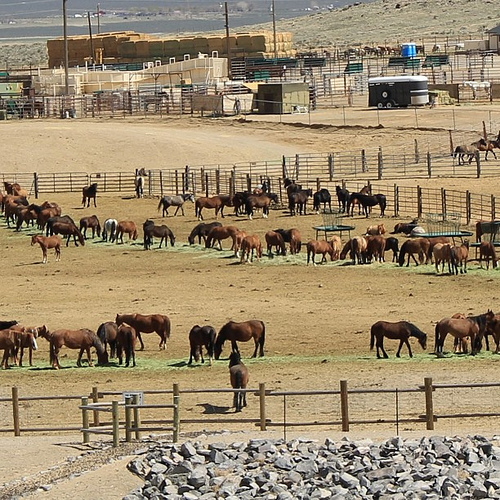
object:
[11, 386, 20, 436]
pole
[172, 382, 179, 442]
pole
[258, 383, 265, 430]
pole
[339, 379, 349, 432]
pole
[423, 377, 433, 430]
pole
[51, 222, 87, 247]
horses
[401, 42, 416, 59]
blue outhouses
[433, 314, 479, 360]
horses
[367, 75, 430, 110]
container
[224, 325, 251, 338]
brown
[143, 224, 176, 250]
horses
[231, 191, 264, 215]
horses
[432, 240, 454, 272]
horses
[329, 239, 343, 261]
horses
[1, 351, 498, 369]
grass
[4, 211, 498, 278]
grass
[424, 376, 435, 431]
fence post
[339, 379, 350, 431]
fence post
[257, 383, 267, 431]
fence post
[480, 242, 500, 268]
horses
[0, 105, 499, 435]
ground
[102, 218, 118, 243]
horse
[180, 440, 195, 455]
rock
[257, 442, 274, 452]
rock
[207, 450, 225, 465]
rock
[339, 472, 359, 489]
rock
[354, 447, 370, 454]
rock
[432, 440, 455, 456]
rock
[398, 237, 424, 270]
horses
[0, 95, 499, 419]
corral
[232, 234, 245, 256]
horses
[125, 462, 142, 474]
rocks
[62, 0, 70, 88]
poles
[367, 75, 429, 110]
horse trailer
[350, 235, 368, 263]
horse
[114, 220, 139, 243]
brown horse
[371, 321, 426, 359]
horse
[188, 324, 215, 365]
horse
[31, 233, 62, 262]
horse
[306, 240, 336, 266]
brown horse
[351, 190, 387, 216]
horse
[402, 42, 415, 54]
portapotties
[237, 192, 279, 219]
horses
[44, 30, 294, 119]
hay bales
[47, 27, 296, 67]
hay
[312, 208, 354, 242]
feed holders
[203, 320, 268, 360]
horse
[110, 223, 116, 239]
tail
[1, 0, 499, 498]
farm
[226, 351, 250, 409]
horse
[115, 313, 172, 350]
horse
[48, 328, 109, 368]
horse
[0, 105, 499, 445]
fence